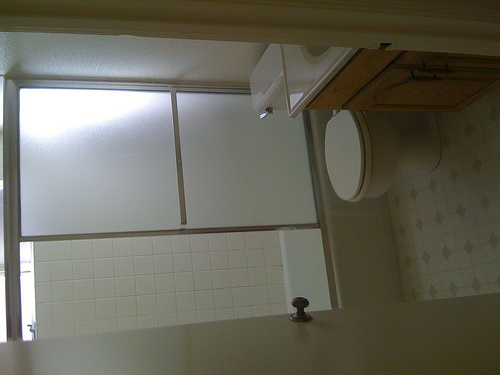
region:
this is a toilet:
[332, 120, 438, 182]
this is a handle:
[290, 297, 310, 322]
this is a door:
[104, 333, 421, 368]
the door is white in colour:
[167, 352, 279, 372]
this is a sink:
[283, 45, 326, 70]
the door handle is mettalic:
[292, 300, 309, 320]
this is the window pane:
[46, 151, 294, 226]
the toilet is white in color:
[337, 126, 404, 170]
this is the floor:
[390, 225, 469, 272]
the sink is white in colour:
[289, 48, 324, 79]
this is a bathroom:
[33, 25, 443, 349]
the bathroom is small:
[18, 38, 443, 348]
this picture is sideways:
[39, 78, 449, 367]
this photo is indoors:
[28, 68, 439, 373]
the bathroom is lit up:
[46, 80, 381, 337]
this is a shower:
[37, 111, 243, 316]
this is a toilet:
[240, 68, 400, 213]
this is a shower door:
[60, 121, 249, 233]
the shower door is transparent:
[27, 121, 213, 226]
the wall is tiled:
[40, 235, 275, 318]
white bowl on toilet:
[321, 110, 446, 216]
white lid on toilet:
[319, 94, 365, 214]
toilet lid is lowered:
[313, 117, 377, 209]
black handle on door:
[276, 267, 336, 329]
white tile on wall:
[88, 234, 259, 342]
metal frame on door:
[10, 84, 325, 233]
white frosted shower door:
[25, 96, 339, 227]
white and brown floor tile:
[402, 162, 468, 289]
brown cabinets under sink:
[330, 79, 495, 131]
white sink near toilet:
[270, 32, 317, 122]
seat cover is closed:
[310, 111, 378, 224]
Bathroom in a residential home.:
[6, 5, 491, 364]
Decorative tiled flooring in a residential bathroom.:
[315, 94, 497, 314]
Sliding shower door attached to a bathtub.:
[4, 30, 375, 374]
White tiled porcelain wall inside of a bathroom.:
[21, 173, 313, 360]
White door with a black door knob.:
[10, 283, 492, 363]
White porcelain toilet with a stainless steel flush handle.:
[225, 45, 431, 225]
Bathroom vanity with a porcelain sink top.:
[275, 35, 491, 137]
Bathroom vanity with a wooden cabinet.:
[277, 38, 497, 123]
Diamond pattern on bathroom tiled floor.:
[369, 101, 497, 313]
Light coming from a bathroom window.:
[0, 43, 235, 156]